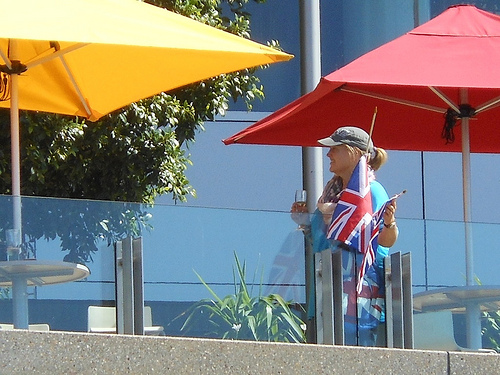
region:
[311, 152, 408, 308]
two small British flags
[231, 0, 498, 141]
large red patio umbrella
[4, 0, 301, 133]
large yellow patio umbrella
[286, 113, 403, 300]
woman wearing a baseball cap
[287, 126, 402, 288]
woman holding a champagne flute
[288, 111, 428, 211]
woman with blonde hair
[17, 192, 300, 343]
glass barrier wall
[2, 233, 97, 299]
small patio table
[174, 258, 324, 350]
green plant on a patio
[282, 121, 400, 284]
woman holding Union Jack flags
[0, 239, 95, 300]
a table on a balcony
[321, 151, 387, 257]
a British flag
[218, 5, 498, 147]
a red umbrella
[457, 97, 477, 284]
an umbrella pole connecting to a table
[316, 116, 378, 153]
a gray cap on a woman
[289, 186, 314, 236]
a drink in a woman's hand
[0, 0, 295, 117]
a yellow umbrella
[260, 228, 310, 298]
the reflection of a British flag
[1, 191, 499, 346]
a glass rail on a balcony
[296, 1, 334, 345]
a tall metal support post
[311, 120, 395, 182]
the head of a woman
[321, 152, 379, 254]
a flag oft the United Kingdom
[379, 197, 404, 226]
the hand of a woman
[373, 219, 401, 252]
the arm of a woman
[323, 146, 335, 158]
the nose of a woman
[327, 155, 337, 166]
the mouth of a woman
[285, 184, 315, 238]
a wine glass in the woman's hand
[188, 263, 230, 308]
a green plant leaf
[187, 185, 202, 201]
the leaf of a tree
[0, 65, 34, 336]
an umbrella pole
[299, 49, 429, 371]
a woman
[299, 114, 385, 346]
a woman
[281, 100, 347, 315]
a woman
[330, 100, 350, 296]
a woman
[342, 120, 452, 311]
a woman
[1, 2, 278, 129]
the umbrella is yellow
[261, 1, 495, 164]
the umbrella is red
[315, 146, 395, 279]
flag is on the balcony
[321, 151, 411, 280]
flag is red white and blue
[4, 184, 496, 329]
structure is made of glass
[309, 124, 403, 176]
woman wearing a hat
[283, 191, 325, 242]
woman holding wine glass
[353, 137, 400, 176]
woman's hair in pony tail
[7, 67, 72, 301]
umbrella handle is white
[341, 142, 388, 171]
woman's hair is blonde